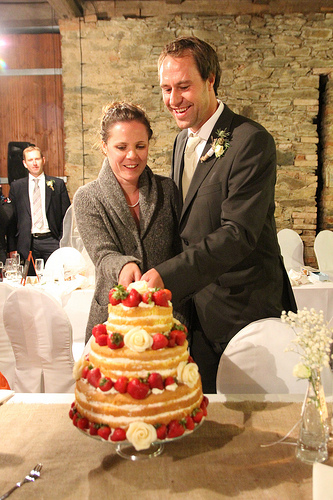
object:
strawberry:
[141, 291, 153, 306]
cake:
[67, 277, 209, 452]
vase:
[293, 363, 329, 466]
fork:
[0, 462, 44, 499]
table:
[0, 393, 333, 500]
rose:
[123, 326, 154, 354]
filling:
[108, 312, 173, 320]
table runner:
[0, 400, 333, 500]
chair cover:
[2, 285, 85, 393]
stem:
[116, 284, 130, 300]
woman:
[73, 96, 195, 358]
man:
[139, 35, 299, 396]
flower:
[214, 145, 224, 158]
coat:
[153, 101, 299, 362]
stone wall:
[57, 14, 333, 271]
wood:
[0, 32, 65, 201]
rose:
[125, 421, 158, 452]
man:
[6, 145, 73, 277]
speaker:
[7, 140, 35, 186]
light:
[0, 36, 8, 50]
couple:
[73, 35, 300, 395]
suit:
[6, 170, 72, 277]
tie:
[181, 135, 202, 206]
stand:
[73, 412, 207, 461]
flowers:
[310, 363, 316, 371]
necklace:
[126, 199, 140, 208]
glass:
[34, 258, 44, 290]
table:
[0, 275, 98, 394]